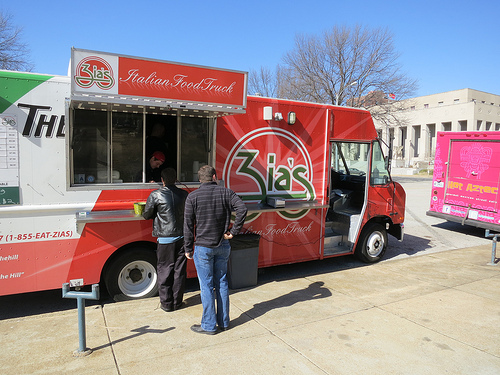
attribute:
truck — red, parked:
[3, 44, 405, 297]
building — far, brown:
[367, 84, 499, 181]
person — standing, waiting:
[184, 163, 246, 337]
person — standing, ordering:
[143, 168, 194, 314]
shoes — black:
[192, 317, 234, 335]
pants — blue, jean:
[190, 237, 234, 332]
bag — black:
[229, 233, 261, 252]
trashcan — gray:
[229, 233, 264, 290]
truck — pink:
[427, 127, 499, 234]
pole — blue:
[59, 280, 107, 354]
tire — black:
[105, 244, 169, 306]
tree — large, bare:
[279, 28, 405, 148]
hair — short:
[197, 165, 221, 181]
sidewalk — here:
[0, 245, 496, 374]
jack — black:
[142, 188, 190, 237]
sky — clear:
[1, 2, 499, 107]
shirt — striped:
[184, 181, 244, 253]